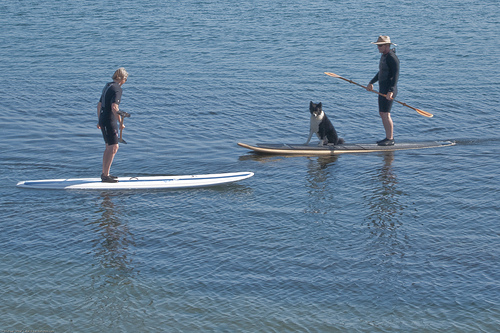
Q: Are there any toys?
A: No, there are no toys.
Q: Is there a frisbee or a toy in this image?
A: No, there are no toys or frisbees.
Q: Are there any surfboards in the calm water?
A: Yes, there are surfboards in the water.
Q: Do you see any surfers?
A: No, there are no surfers.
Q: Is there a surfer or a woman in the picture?
A: No, there are no surfers or women.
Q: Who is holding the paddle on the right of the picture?
A: The man is holding the oar.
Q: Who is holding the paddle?
A: The man is holding the oar.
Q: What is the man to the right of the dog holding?
A: The man is holding the paddle.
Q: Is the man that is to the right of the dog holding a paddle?
A: Yes, the man is holding a paddle.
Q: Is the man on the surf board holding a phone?
A: No, the man is holding a paddle.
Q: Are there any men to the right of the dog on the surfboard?
A: Yes, there is a man to the right of the dog.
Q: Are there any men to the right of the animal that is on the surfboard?
A: Yes, there is a man to the right of the dog.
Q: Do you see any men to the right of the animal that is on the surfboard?
A: Yes, there is a man to the right of the dog.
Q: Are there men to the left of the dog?
A: No, the man is to the right of the dog.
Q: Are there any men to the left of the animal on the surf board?
A: No, the man is to the right of the dog.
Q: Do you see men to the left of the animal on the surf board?
A: No, the man is to the right of the dog.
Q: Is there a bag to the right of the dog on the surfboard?
A: No, there is a man to the right of the dog.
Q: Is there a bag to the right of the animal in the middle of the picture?
A: No, there is a man to the right of the dog.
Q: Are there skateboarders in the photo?
A: No, there are no skateboarders.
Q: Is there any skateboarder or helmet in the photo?
A: No, there are no skateboarders or helmets.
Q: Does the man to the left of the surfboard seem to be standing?
A: Yes, the man is standing.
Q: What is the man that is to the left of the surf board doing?
A: The man is standing.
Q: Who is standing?
A: The man is standing.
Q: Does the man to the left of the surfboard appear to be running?
A: No, the man is standing.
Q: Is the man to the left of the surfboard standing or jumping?
A: The man is standing.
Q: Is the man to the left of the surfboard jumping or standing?
A: The man is standing.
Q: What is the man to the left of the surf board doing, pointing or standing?
A: The man is standing.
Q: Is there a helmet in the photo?
A: No, there are no helmets.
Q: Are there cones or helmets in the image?
A: No, there are no helmets or cones.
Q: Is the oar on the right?
A: Yes, the oar is on the right of the image.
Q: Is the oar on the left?
A: No, the oar is on the right of the image.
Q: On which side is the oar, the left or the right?
A: The oar is on the right of the image.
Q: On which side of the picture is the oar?
A: The oar is on the right of the image.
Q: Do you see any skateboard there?
A: No, there are no skateboards.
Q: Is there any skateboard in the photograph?
A: No, there are no skateboards.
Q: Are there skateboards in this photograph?
A: No, there are no skateboards.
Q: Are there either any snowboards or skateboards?
A: No, there are no skateboards or snowboards.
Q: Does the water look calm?
A: Yes, the water is calm.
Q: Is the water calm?
A: Yes, the water is calm.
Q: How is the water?
A: The water is calm.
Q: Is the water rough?
A: No, the water is calm.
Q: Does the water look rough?
A: No, the water is calm.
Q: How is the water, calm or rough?
A: The water is calm.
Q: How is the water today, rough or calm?
A: The water is calm.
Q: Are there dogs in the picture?
A: Yes, there is a dog.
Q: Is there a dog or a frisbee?
A: Yes, there is a dog.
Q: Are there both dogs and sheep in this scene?
A: No, there is a dog but no sheep.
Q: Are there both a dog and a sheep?
A: No, there is a dog but no sheep.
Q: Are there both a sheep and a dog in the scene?
A: No, there is a dog but no sheep.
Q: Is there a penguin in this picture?
A: No, there are no penguins.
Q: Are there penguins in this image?
A: No, there are no penguins.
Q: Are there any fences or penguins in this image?
A: No, there are no penguins or fences.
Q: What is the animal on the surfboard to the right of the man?
A: The animal is a dog.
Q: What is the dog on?
A: The dog is on the surfboard.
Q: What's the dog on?
A: The dog is on the surfboard.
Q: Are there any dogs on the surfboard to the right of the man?
A: Yes, there is a dog on the surf board.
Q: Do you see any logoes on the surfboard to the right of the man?
A: No, there is a dog on the surf board.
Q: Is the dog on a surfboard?
A: Yes, the dog is on a surfboard.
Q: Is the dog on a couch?
A: No, the dog is on a surfboard.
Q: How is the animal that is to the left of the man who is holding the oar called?
A: The animal is a dog.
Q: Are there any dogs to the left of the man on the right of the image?
A: Yes, there is a dog to the left of the man.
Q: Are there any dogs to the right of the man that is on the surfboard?
A: No, the dog is to the left of the man.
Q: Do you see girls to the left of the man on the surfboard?
A: No, there is a dog to the left of the man.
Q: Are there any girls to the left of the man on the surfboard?
A: No, there is a dog to the left of the man.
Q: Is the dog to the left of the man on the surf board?
A: Yes, the dog is to the left of the man.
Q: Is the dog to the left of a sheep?
A: No, the dog is to the left of the man.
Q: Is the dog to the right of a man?
A: No, the dog is to the left of a man.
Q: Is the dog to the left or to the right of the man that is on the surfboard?
A: The dog is to the left of the man.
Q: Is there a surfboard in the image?
A: Yes, there is a surfboard.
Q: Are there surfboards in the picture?
A: Yes, there is a surfboard.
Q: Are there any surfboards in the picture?
A: Yes, there is a surfboard.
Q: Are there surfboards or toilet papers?
A: Yes, there is a surfboard.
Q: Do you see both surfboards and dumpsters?
A: No, there is a surfboard but no dumpsters.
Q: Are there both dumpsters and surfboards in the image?
A: No, there is a surfboard but no dumpsters.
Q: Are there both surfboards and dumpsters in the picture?
A: No, there is a surfboard but no dumpsters.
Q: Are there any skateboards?
A: No, there are no skateboards.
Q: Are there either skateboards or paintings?
A: No, there are no skateboards or paintings.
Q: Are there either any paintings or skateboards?
A: No, there are no skateboards or paintings.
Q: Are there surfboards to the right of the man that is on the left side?
A: Yes, there is a surfboard to the right of the man.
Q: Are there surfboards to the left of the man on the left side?
A: No, the surfboard is to the right of the man.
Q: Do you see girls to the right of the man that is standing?
A: No, there is a surfboard to the right of the man.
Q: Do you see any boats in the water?
A: No, there is a surfboard in the water.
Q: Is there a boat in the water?
A: No, there is a surfboard in the water.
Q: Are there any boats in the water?
A: No, there is a surfboard in the water.